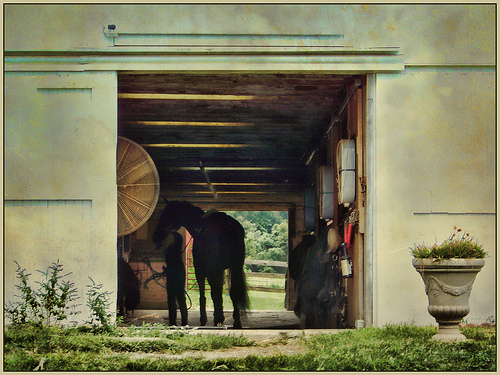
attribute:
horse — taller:
[151, 199, 254, 331]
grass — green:
[0, 311, 499, 372]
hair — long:
[225, 226, 251, 306]